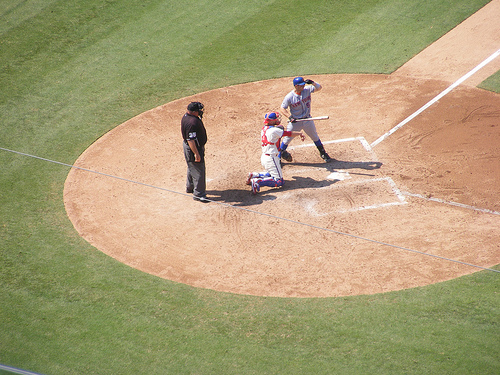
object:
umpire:
[177, 100, 214, 206]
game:
[2, 2, 498, 301]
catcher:
[245, 109, 308, 201]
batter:
[272, 69, 340, 164]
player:
[281, 76, 332, 162]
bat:
[286, 112, 331, 125]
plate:
[327, 166, 355, 183]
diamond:
[263, 133, 408, 219]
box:
[261, 130, 411, 221]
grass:
[2, 0, 500, 375]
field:
[1, 1, 497, 375]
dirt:
[61, 1, 499, 298]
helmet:
[263, 112, 283, 129]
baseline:
[367, 51, 499, 150]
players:
[160, 48, 345, 225]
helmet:
[182, 98, 210, 120]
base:
[315, 164, 363, 184]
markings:
[0, 59, 499, 220]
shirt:
[175, 110, 210, 148]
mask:
[196, 102, 206, 120]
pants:
[180, 141, 206, 202]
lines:
[402, 190, 500, 217]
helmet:
[284, 75, 309, 92]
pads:
[275, 178, 285, 188]